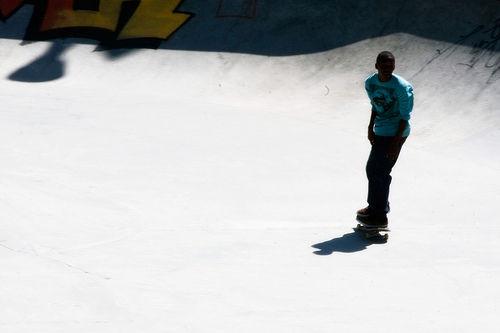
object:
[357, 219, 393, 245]
skate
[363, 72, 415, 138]
shirt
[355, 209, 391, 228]
shoes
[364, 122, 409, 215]
pants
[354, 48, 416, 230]
boy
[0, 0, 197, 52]
graffiti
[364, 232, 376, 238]
wheels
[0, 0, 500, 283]
ramp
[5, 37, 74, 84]
shadow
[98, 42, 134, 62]
shadow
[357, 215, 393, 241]
skateboard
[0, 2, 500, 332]
park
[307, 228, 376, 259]
shadow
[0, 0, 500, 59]
shadow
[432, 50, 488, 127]
marks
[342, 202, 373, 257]
front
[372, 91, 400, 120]
decal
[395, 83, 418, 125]
wrinkles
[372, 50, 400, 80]
head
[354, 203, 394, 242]
ridden